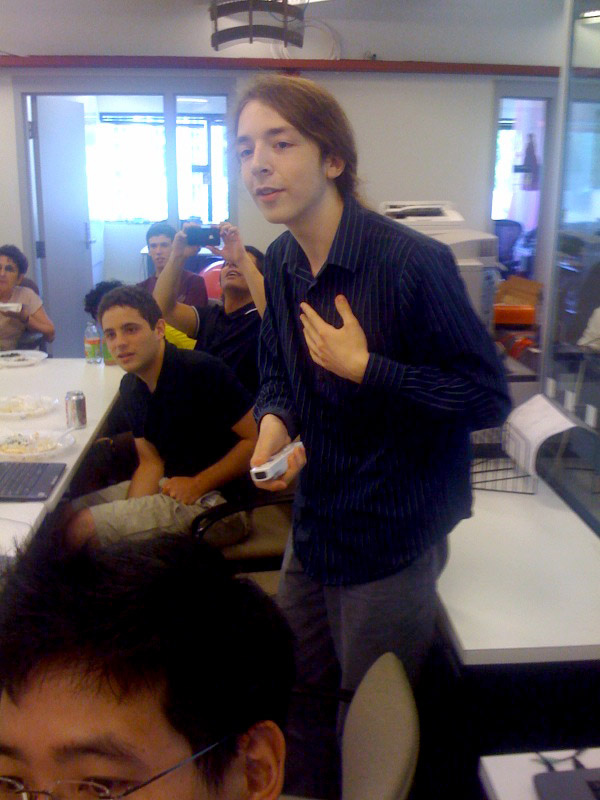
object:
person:
[132, 222, 207, 348]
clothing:
[116, 343, 258, 502]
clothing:
[188, 294, 269, 384]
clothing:
[250, 202, 513, 592]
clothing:
[133, 268, 207, 315]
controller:
[250, 441, 305, 483]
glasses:
[0, 722, 278, 800]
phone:
[183, 226, 221, 247]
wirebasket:
[471, 420, 538, 494]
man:
[230, 75, 513, 701]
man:
[0, 528, 330, 800]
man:
[151, 222, 266, 396]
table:
[435, 489, 600, 667]